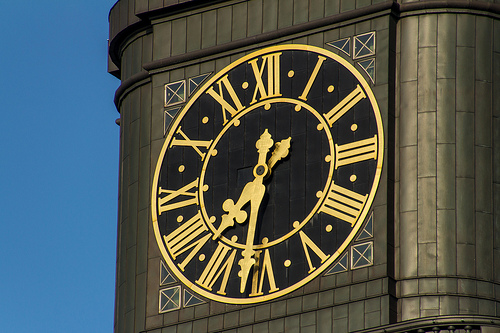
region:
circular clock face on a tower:
[145, 29, 386, 314]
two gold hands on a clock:
[203, 128, 308, 300]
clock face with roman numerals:
[138, 33, 394, 320]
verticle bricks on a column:
[415, 36, 483, 286]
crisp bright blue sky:
[15, 61, 99, 233]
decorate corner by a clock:
[150, 268, 208, 320]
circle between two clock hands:
[252, 161, 267, 181]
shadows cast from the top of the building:
[114, 13, 201, 55]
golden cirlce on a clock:
[200, 111, 210, 128]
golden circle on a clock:
[174, 160, 189, 175]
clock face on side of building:
[142, 28, 387, 315]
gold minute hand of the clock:
[231, 128, 275, 290]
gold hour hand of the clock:
[201, 131, 291, 238]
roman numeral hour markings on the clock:
[137, 52, 390, 308]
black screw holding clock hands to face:
[251, 161, 269, 176]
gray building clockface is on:
[108, 3, 488, 332]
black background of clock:
[134, 47, 393, 304]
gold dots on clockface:
[155, 58, 370, 282]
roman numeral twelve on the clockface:
[240, 50, 285, 104]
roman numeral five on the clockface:
[291, 227, 331, 275]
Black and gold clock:
[149, 36, 395, 313]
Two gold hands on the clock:
[208, 124, 307, 298]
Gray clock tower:
[99, 2, 497, 332]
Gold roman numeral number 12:
[247, 53, 294, 110]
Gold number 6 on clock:
[246, 248, 282, 295]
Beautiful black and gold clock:
[151, 28, 367, 332]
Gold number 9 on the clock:
[146, 179, 218, 217]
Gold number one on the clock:
[300, 42, 325, 113]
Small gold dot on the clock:
[314, 78, 341, 99]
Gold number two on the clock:
[315, 81, 381, 135]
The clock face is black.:
[141, 34, 388, 312]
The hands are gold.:
[128, 41, 388, 305]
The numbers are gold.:
[128, 41, 394, 296]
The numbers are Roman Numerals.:
[118, 34, 395, 296]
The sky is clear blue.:
[0, 1, 125, 324]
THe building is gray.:
[90, 6, 475, 331]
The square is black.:
[334, 238, 392, 265]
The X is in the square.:
[334, 238, 378, 273]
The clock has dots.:
[125, 56, 389, 311]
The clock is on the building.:
[116, 34, 494, 330]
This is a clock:
[138, 38, 400, 308]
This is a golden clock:
[145, 40, 395, 310]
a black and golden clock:
[144, 40, 390, 316]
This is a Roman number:
[288, 223, 341, 282]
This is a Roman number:
[313, 175, 383, 233]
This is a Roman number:
[323, 133, 400, 173]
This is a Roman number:
[311, 79, 368, 133]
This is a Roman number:
[290, 50, 330, 110]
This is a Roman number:
[243, 49, 288, 111]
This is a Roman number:
[205, 68, 252, 126]